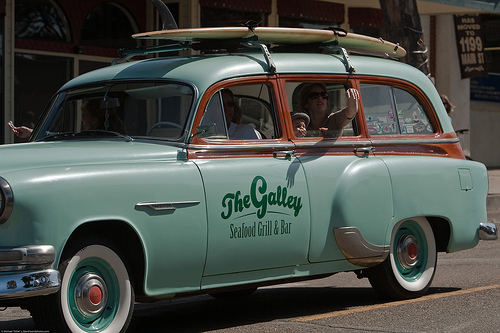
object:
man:
[220, 88, 263, 139]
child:
[287, 111, 310, 137]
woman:
[299, 82, 359, 137]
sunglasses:
[224, 100, 234, 108]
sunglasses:
[309, 91, 329, 99]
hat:
[291, 113, 310, 129]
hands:
[297, 127, 328, 137]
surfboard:
[132, 26, 407, 58]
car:
[1, 26, 489, 333]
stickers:
[364, 108, 435, 135]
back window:
[192, 75, 443, 141]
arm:
[330, 94, 359, 129]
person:
[11, 99, 113, 139]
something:
[5, 121, 20, 136]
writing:
[221, 175, 303, 238]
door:
[190, 84, 310, 277]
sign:
[455, 14, 489, 79]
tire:
[61, 242, 136, 333]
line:
[298, 284, 500, 322]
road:
[3, 249, 497, 331]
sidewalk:
[481, 166, 500, 197]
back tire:
[368, 216, 437, 299]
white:
[232, 127, 251, 138]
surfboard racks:
[122, 44, 362, 74]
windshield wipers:
[35, 129, 133, 142]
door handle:
[274, 150, 294, 155]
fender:
[332, 226, 391, 267]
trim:
[183, 75, 463, 159]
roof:
[57, 25, 437, 93]